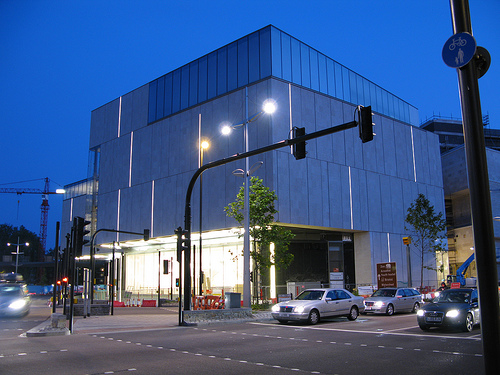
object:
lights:
[198, 138, 210, 150]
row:
[147, 23, 419, 127]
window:
[271, 24, 282, 78]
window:
[289, 36, 303, 86]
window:
[228, 42, 237, 91]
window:
[162, 73, 173, 117]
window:
[342, 65, 352, 102]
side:
[270, 24, 450, 303]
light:
[259, 96, 277, 115]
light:
[218, 123, 234, 137]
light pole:
[183, 104, 375, 312]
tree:
[223, 175, 297, 305]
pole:
[243, 85, 251, 307]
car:
[271, 287, 368, 324]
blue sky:
[1, 2, 155, 77]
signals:
[289, 127, 308, 161]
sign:
[376, 262, 397, 290]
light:
[287, 104, 376, 160]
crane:
[0, 176, 65, 255]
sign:
[441, 31, 477, 68]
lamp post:
[219, 86, 280, 307]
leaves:
[250, 186, 293, 271]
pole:
[447, 0, 499, 375]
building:
[88, 22, 450, 304]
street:
[3, 292, 484, 372]